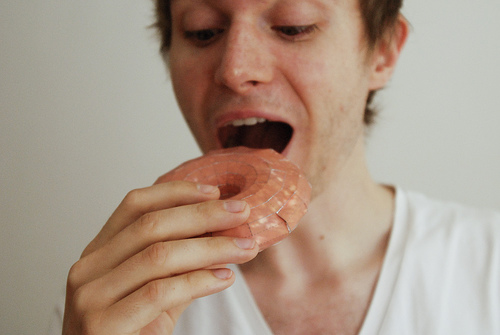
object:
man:
[63, 0, 500, 335]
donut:
[153, 147, 312, 251]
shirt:
[45, 184, 499, 335]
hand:
[61, 182, 261, 334]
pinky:
[112, 269, 236, 335]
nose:
[214, 10, 274, 93]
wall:
[2, 1, 499, 335]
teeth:
[224, 117, 270, 125]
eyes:
[270, 24, 317, 41]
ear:
[367, 13, 408, 92]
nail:
[196, 184, 219, 199]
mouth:
[210, 107, 298, 161]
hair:
[150, 0, 402, 128]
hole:
[216, 181, 242, 198]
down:
[1, 329, 499, 335]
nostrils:
[241, 77, 261, 92]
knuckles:
[67, 282, 103, 312]